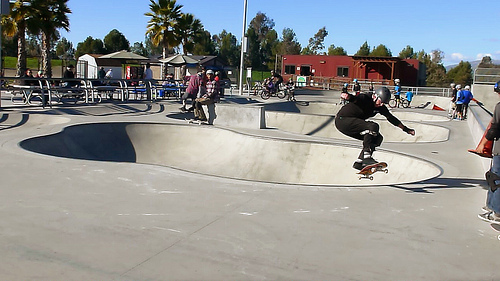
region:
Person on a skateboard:
[319, 71, 399, 194]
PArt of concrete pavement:
[42, 220, 84, 279]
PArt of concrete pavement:
[111, 221, 141, 268]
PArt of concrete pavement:
[177, 211, 224, 279]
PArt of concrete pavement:
[255, 231, 296, 278]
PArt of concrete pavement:
[318, 221, 358, 271]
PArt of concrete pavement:
[51, 186, 122, 241]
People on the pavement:
[175, 60, 214, 135]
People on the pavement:
[390, 69, 473, 125]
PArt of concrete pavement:
[38, 119, 193, 224]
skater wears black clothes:
[325, 75, 428, 185]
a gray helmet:
[355, 75, 396, 115]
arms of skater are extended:
[318, 73, 418, 185]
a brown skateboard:
[356, 155, 393, 180]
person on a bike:
[383, 75, 413, 112]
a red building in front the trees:
[274, 43, 430, 91]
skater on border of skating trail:
[322, 79, 435, 199]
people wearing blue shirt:
[448, 83, 476, 120]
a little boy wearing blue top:
[402, 82, 416, 105]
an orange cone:
[466, 113, 498, 167]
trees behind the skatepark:
[2, 0, 498, 87]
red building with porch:
[276, 49, 431, 95]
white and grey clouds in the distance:
[420, 45, 499, 68]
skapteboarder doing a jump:
[332, 78, 424, 183]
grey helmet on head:
[372, 82, 395, 110]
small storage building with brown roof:
[70, 48, 133, 90]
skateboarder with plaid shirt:
[197, 70, 227, 127]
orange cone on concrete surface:
[470, 108, 499, 168]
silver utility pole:
[237, 0, 252, 106]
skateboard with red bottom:
[350, 160, 400, 190]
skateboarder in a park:
[323, 71, 425, 198]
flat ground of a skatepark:
[33, 180, 281, 258]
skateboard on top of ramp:
[348, 155, 394, 182]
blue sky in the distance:
[338, 3, 483, 38]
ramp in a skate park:
[41, 112, 412, 209]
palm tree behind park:
[143, 3, 198, 50]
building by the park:
[271, 48, 434, 98]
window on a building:
[332, 63, 352, 81]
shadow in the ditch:
[26, 120, 133, 175]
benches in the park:
[20, 71, 167, 103]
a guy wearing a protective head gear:
[327, 77, 427, 179]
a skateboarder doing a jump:
[320, 86, 427, 183]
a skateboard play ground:
[6, 37, 489, 279]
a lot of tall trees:
[0, 2, 205, 82]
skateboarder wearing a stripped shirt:
[185, 62, 228, 127]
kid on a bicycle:
[381, 78, 423, 107]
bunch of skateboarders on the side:
[437, 75, 474, 118]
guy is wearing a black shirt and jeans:
[315, 79, 430, 179]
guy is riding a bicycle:
[254, 68, 294, 100]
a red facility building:
[274, 45, 431, 89]